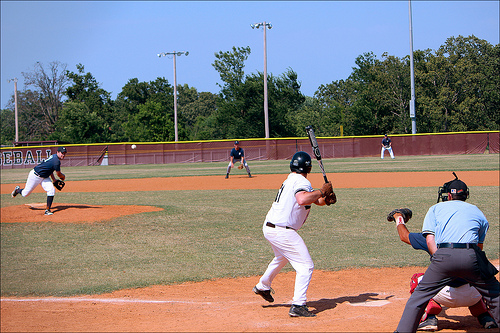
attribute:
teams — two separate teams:
[16, 117, 463, 327]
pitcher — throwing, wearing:
[12, 148, 71, 218]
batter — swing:
[252, 151, 323, 313]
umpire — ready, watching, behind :
[395, 170, 499, 333]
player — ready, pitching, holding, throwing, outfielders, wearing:
[9, 138, 499, 326]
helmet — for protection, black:
[292, 148, 311, 174]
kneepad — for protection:
[411, 270, 422, 290]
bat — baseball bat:
[306, 123, 341, 202]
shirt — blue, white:
[37, 153, 62, 180]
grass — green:
[0, 151, 499, 295]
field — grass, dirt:
[0, 148, 499, 333]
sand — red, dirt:
[4, 170, 499, 333]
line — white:
[0, 289, 403, 333]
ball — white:
[132, 143, 137, 151]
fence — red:
[5, 132, 499, 158]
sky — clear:
[1, 1, 499, 111]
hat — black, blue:
[56, 145, 70, 157]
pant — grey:
[394, 245, 499, 330]